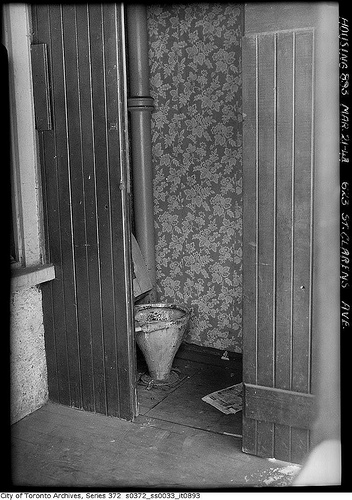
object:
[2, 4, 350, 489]
photo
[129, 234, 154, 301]
lid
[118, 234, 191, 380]
toilet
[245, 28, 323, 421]
surface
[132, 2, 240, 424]
doorway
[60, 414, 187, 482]
surface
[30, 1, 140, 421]
door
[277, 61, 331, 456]
wood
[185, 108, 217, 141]
flower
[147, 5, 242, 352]
wallpaper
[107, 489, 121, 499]
label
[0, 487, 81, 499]
archives label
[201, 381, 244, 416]
newspaper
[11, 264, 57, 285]
window sill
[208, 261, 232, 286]
pattern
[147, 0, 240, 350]
wall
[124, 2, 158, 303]
pipe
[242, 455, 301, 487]
white paint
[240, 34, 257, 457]
wooden plank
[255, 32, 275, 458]
wooden plank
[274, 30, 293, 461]
wooden plank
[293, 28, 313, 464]
wooden plank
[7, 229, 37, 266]
corner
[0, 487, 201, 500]
serial identification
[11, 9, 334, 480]
bathroom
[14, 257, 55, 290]
surface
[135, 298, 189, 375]
dirt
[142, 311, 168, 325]
feces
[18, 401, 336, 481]
floor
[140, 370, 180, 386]
hole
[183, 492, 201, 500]
number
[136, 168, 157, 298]
water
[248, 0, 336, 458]
paneling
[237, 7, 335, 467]
door